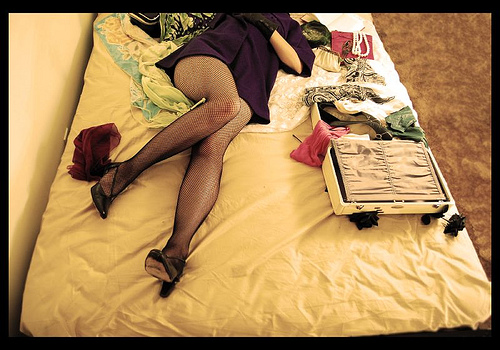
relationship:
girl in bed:
[89, 0, 317, 298] [85, 46, 472, 310]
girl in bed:
[89, 0, 317, 298] [54, 43, 462, 345]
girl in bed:
[89, 0, 317, 298] [65, 33, 442, 310]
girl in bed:
[89, 0, 317, 298] [84, 43, 442, 343]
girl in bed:
[89, 0, 317, 298] [96, 49, 463, 328]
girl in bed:
[89, 0, 317, 298] [80, 39, 474, 339]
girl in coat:
[89, 0, 317, 298] [181, 35, 290, 112]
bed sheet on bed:
[16, 8, 493, 336] [47, 47, 455, 316]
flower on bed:
[433, 214, 466, 238] [95, 71, 475, 348]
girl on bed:
[89, 0, 317, 298] [59, 7, 473, 348]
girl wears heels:
[89, 0, 317, 298] [71, 120, 207, 319]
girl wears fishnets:
[89, 0, 317, 298] [101, 55, 253, 262]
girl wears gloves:
[89, 0, 317, 298] [254, 20, 286, 45]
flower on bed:
[429, 181, 473, 244] [59, 7, 473, 348]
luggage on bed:
[309, 79, 456, 231] [67, 21, 476, 333]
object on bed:
[61, 118, 160, 245] [67, 21, 476, 333]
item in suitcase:
[368, 110, 435, 161] [309, 99, 433, 260]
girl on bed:
[94, 26, 396, 323] [67, 21, 476, 333]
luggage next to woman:
[309, 79, 456, 231] [90, 3, 326, 278]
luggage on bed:
[309, 79, 456, 231] [21, 11, 498, 343]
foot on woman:
[137, 234, 188, 314] [71, 33, 331, 297]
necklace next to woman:
[349, 28, 372, 58] [93, 18, 323, 305]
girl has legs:
[89, 0, 317, 298] [91, 58, 252, 301]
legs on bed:
[91, 58, 252, 301] [14, 11, 497, 314]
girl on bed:
[89, 0, 317, 298] [14, 11, 497, 314]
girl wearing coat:
[89, 0, 317, 298] [155, 12, 315, 125]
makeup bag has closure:
[302, 43, 344, 76] [308, 38, 341, 61]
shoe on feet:
[84, 157, 114, 222] [76, 152, 128, 220]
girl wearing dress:
[89, 0, 317, 298] [152, 4, 314, 131]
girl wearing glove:
[89, 0, 317, 298] [228, 1, 274, 40]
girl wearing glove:
[89, 0, 317, 298] [229, 7, 276, 37]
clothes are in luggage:
[293, 74, 426, 174] [302, 79, 458, 234]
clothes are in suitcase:
[290, 80, 428, 172] [293, 80, 467, 234]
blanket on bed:
[28, 9, 491, 334] [21, 11, 498, 343]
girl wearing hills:
[89, 0, 317, 298] [99, 48, 251, 263]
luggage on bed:
[302, 79, 458, 234] [21, 11, 498, 343]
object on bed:
[65, 119, 120, 182] [21, 11, 498, 343]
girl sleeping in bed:
[89, 0, 317, 298] [21, 11, 498, 343]